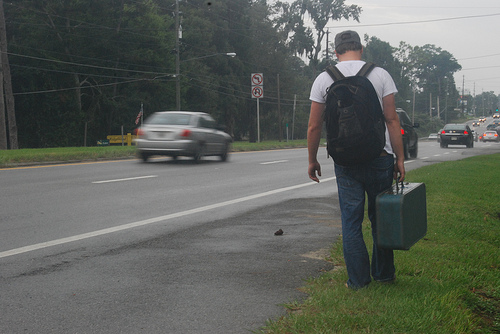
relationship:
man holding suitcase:
[305, 31, 405, 291] [373, 180, 430, 251]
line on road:
[2, 158, 418, 259] [1, 114, 497, 276]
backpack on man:
[325, 59, 385, 168] [305, 31, 405, 291]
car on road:
[133, 108, 233, 163] [1, 114, 497, 276]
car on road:
[440, 122, 475, 148] [1, 114, 497, 276]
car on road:
[392, 108, 420, 159] [1, 114, 497, 276]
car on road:
[484, 131, 499, 143] [1, 114, 497, 276]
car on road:
[426, 131, 440, 142] [1, 114, 497, 276]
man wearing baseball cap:
[305, 31, 405, 291] [332, 31, 361, 46]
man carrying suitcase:
[305, 31, 405, 291] [373, 180, 430, 251]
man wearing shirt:
[305, 31, 405, 291] [309, 60, 400, 159]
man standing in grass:
[305, 31, 405, 291] [261, 150, 499, 333]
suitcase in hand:
[373, 180, 430, 251] [391, 164, 408, 183]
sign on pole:
[251, 73, 263, 87] [256, 98, 261, 143]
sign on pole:
[251, 85, 264, 99] [256, 98, 261, 143]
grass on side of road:
[261, 150, 499, 333] [1, 114, 497, 276]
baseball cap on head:
[332, 31, 361, 46] [333, 32, 364, 59]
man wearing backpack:
[305, 31, 405, 291] [325, 59, 385, 168]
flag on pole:
[134, 105, 144, 126] [140, 102, 145, 125]